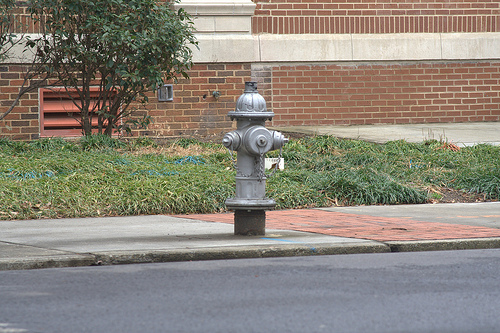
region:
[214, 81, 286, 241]
Silver fire hydrant on sidewalk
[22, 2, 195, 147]
Green shrub next to building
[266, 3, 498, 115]
Grey brick wall outlined with white trimming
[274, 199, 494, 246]
Grey sidewalk lined with red brick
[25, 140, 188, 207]
Green grass outlined the scenery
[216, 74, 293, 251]
Tall silver fire hydrant with three attachments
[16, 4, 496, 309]
Scene that portrays tall silver fire hydrant on sidewalk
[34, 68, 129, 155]
Red vent on side of building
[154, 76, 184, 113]
Silver electrical attachment on side of building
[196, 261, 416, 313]
Dark grey streets lined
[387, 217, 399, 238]
black mark is spotted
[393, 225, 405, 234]
black mark is spotted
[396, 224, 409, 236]
black mark is spotted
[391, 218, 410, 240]
black mark is spotted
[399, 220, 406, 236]
black mark is spotted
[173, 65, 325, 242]
hydrant next to street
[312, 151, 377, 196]
green grass next to hydrant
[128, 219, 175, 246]
gray sidewalk next to hydrant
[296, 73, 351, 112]
red brick wall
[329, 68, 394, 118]
wall next to grass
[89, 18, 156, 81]
leaves on a tree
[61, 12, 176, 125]
tree above the grass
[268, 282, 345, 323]
street next to hydrant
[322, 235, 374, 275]
curb next to street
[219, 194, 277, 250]
base of the hydrant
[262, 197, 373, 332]
the ground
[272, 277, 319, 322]
the ground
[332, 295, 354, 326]
the ground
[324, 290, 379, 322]
the ground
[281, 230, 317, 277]
the ground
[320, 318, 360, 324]
the ground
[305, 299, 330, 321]
the ground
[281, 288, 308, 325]
the ground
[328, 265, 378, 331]
the ground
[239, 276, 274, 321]
the road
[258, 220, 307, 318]
the road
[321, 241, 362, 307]
the road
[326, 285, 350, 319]
the road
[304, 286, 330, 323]
the road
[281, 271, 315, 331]
the road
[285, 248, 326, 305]
the road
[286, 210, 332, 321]
the road